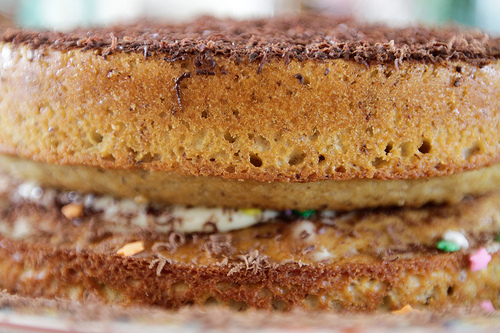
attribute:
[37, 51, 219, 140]
crust — golden 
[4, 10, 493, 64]
top — dark brown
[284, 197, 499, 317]
sprinkles — shapes 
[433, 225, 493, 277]
star — pink, green, white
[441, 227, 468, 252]
sprinkle — white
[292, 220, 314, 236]
sprinkle — white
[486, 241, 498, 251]
sprinkle — white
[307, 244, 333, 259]
sprinkle — white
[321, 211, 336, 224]
sprinkle — white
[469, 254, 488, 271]
sprinkle — pink 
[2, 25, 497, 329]
cake — dessert, golden brown, golden, brown, layer, light brown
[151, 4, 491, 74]
chocolate — dark brown, grated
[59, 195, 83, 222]
sprinkle — orange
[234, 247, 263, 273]
shavings — chocolate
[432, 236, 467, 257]
sprinkle — green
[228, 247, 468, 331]
crust — bottom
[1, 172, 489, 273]
shaving — chocolate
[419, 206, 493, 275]
confetti — pink, green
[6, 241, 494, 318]
holes — spongy 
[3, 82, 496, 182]
holes — spongy 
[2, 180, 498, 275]
chocolate — grated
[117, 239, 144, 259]
orange confetti — small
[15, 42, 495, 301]
crusty cake — toasty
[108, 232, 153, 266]
sprinkle — orange, star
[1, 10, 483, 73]
crust — top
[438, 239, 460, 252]
sprinkle — green, star shaped